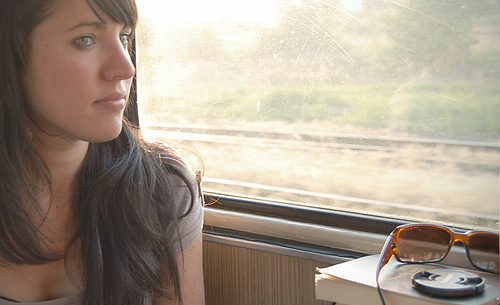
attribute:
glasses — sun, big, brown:
[371, 220, 483, 303]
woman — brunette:
[3, 1, 209, 302]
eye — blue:
[69, 30, 97, 49]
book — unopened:
[310, 248, 484, 303]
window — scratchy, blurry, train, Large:
[134, 0, 484, 236]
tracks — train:
[139, 116, 484, 232]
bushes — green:
[202, 79, 484, 136]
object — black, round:
[409, 264, 484, 300]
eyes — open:
[67, 33, 132, 48]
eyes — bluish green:
[66, 31, 130, 51]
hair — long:
[0, 0, 216, 302]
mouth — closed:
[93, 88, 127, 108]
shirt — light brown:
[5, 153, 205, 301]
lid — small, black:
[410, 266, 485, 296]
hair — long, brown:
[3, 0, 195, 302]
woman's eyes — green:
[68, 29, 132, 48]